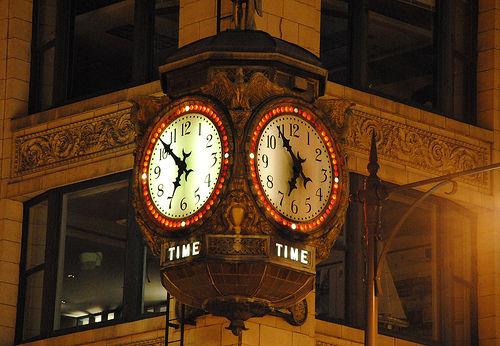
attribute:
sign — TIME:
[166, 237, 204, 263]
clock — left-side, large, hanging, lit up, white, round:
[135, 96, 236, 232]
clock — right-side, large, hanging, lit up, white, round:
[241, 93, 344, 238]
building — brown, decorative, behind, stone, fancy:
[1, 1, 499, 344]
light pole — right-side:
[353, 123, 497, 345]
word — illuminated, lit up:
[167, 238, 202, 263]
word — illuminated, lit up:
[274, 238, 310, 267]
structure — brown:
[130, 28, 355, 337]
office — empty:
[26, 182, 168, 340]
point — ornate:
[360, 126, 383, 181]